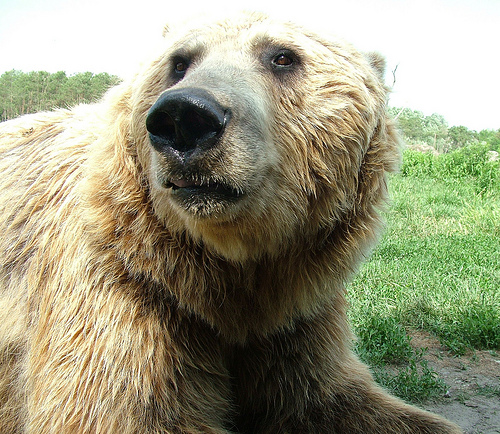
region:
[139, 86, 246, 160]
Large black bear nose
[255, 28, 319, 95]
Small brown bear eye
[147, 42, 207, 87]
Small brown bear eye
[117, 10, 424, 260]
Large head of brown bear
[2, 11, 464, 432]
Large brown bear staring at camera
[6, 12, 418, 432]
Curious looking brown bear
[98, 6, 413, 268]
Large bear face with mouth slightly open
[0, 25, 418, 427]
Large bear with brown hair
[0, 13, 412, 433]
Large bear with brown fur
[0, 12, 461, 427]
Bear looking at camera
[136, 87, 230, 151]
a big wet nose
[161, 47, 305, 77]
a pair of brown eyes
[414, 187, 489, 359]
patches of thick green grass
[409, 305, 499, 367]
patches of dirt in the grass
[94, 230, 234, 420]
long brown animal fur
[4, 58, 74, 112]
a field of trees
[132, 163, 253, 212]
a wet animal mouth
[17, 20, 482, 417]
a large brown bear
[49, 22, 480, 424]
close up of wild animal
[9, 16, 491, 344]
green landscape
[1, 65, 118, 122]
green trees in a distance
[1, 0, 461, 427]
a nice looking dog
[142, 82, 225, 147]
black nose of a dog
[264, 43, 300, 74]
right eye of a dog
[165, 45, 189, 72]
left eye of a dog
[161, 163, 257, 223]
the mouth of a dog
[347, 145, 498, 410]
green healthy grass can be seen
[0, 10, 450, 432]
a dog covered with fur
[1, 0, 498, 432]
it is a daytime scene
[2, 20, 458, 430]
a cute dog with brown fur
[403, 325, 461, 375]
clear path by green grass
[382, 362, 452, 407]
small section of green grass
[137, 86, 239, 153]
black nose on dog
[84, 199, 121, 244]
small section of dog hair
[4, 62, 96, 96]
green trees in the background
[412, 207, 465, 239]
clear patch of green grass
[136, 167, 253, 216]
dog's closed mouth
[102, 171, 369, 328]
dog's over sized neck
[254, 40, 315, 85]
dog's mournful eyes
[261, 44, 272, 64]
black spot on dog's eye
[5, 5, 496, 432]
the photo is clear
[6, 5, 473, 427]
the photo was taken during the day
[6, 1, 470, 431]
the photo was taken outside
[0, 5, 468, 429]
an animal is in the photo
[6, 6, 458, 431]
the animal is a bear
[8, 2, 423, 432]
the animal is brown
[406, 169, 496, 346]
grass is green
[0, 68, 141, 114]
trees are seen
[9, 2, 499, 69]
the sky is clear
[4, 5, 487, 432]
nobody is in the photo